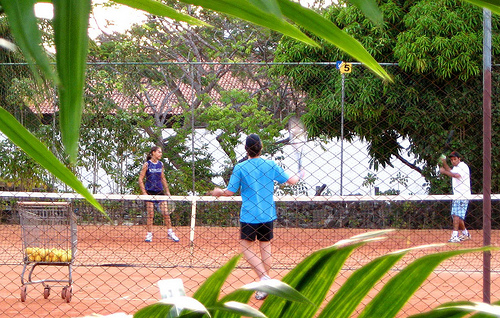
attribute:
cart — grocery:
[17, 198, 77, 307]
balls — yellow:
[24, 242, 75, 265]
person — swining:
[216, 133, 305, 274]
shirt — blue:
[228, 157, 289, 221]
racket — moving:
[292, 148, 317, 187]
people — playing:
[142, 142, 477, 246]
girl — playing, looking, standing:
[141, 147, 179, 243]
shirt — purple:
[140, 161, 170, 202]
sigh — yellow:
[336, 62, 353, 75]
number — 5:
[341, 64, 351, 75]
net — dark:
[7, 191, 500, 273]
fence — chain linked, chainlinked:
[96, 72, 353, 126]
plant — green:
[5, 3, 136, 233]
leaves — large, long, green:
[49, 8, 92, 163]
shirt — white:
[446, 163, 478, 203]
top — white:
[3, 187, 204, 205]